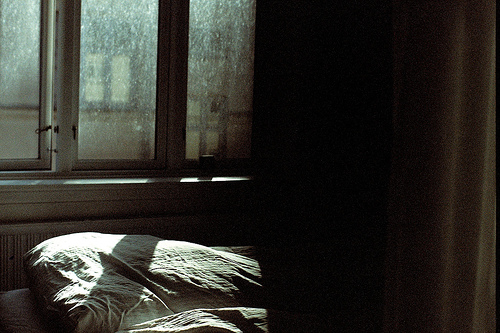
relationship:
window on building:
[85, 43, 138, 113] [3, 3, 238, 113]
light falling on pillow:
[56, 221, 136, 293] [71, 228, 275, 325]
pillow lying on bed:
[71, 228, 275, 325] [9, 283, 65, 333]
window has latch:
[85, 43, 138, 113] [34, 118, 52, 143]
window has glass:
[85, 43, 138, 113] [78, 2, 145, 163]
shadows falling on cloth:
[83, 227, 157, 305] [40, 249, 194, 315]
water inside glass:
[202, 159, 212, 174] [200, 144, 215, 188]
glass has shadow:
[200, 144, 215, 188] [164, 180, 216, 196]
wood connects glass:
[55, 122, 74, 176] [78, 2, 145, 163]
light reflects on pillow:
[56, 221, 136, 293] [71, 228, 275, 325]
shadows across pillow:
[83, 227, 157, 305] [71, 228, 275, 325]